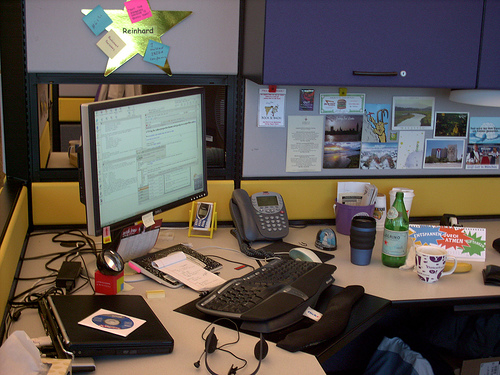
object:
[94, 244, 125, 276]
computer mouse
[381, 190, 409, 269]
bottle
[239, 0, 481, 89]
cabinet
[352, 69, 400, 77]
handle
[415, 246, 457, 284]
cup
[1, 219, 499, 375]
desk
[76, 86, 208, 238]
monitor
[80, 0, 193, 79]
star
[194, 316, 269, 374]
headpiece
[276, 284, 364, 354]
armrest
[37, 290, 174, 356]
laptop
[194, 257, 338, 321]
keyboard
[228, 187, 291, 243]
telephone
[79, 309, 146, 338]
cd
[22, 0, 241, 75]
door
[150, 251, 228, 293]
notebook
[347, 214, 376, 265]
coffee mug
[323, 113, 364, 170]
picture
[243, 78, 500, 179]
wall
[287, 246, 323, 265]
computer mouse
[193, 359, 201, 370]
microphone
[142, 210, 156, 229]
post it note